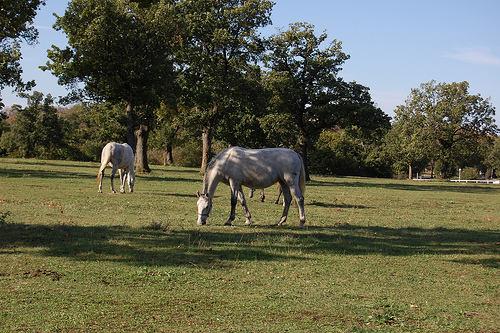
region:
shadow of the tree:
[99, 200, 447, 277]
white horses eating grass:
[81, 124, 320, 232]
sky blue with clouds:
[367, 11, 482, 72]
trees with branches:
[105, 17, 322, 133]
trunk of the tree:
[130, 126, 150, 171]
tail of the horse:
[295, 150, 310, 195]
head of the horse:
[185, 186, 215, 226]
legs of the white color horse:
[225, 180, 255, 230]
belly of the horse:
[248, 161, 271, 191]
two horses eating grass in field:
[78, 133, 323, 235]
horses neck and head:
[189, 168, 224, 230]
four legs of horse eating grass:
[222, 185, 316, 230]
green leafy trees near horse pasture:
[5, 6, 497, 176]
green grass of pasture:
[7, 158, 492, 325]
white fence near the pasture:
[409, 171, 496, 191]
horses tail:
[294, 153, 311, 200]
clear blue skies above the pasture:
[293, 5, 493, 97]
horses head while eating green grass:
[188, 188, 215, 231]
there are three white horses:
[92, 135, 310, 231]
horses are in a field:
[95, 138, 308, 233]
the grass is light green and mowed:
[0, 155, 497, 330]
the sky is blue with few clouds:
[0, 0, 498, 180]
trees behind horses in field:
[0, 1, 382, 182]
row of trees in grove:
[1, 87, 429, 178]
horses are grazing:
[95, 137, 307, 227]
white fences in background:
[408, 166, 498, 182]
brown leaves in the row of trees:
[2, 95, 180, 165]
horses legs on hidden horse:
[246, 180, 290, 207]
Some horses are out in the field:
[28, 22, 478, 325]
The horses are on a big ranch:
[6, 27, 482, 308]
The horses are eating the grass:
[8, 36, 481, 316]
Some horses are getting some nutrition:
[12, 47, 483, 313]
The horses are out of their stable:
[3, 41, 496, 317]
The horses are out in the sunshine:
[25, 36, 486, 311]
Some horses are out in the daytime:
[6, 40, 483, 330]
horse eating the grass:
[185, 165, 326, 225]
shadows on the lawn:
[18, 223, 499, 275]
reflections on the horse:
[221, 138, 344, 224]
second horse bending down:
[88, 149, 164, 194]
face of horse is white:
[187, 186, 213, 236]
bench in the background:
[436, 178, 496, 183]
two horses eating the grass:
[66, 125, 348, 237]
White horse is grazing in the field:
[194, 145, 314, 230]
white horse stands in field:
[97, 138, 139, 193]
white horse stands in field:
[197, 146, 311, 232]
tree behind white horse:
[46, 0, 271, 174]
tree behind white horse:
[164, 0, 276, 173]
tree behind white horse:
[247, 17, 390, 184]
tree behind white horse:
[385, 74, 499, 187]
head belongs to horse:
[194, 191, 215, 228]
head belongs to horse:
[125, 171, 138, 194]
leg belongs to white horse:
[223, 180, 242, 225]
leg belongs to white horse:
[285, 175, 307, 227]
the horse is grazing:
[196, 145, 306, 227]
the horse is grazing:
[97, 143, 134, 195]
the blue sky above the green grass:
[0, 0, 499, 332]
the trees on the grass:
[1, 0, 498, 329]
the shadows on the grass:
[1, 156, 498, 330]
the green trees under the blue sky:
[1, 0, 499, 178]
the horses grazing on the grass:
[1, 143, 499, 332]